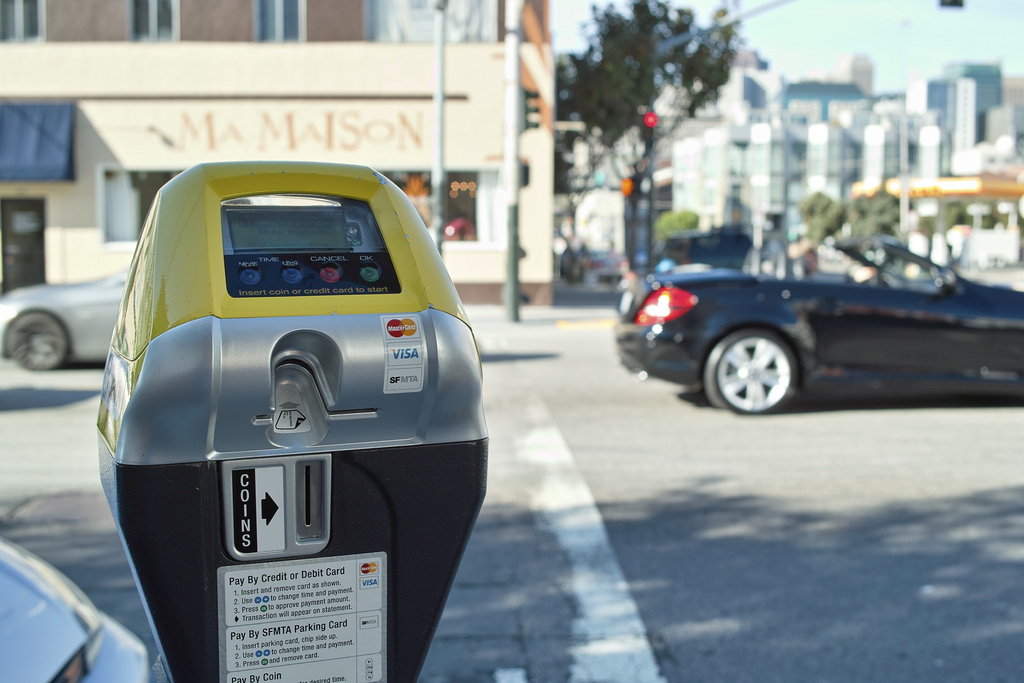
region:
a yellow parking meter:
[91, 149, 490, 678]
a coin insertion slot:
[223, 450, 332, 561]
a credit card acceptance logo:
[382, 313, 428, 396]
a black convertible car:
[607, 234, 1022, 418]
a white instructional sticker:
[218, 551, 392, 679]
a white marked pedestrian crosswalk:
[464, 351, 671, 677]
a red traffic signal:
[641, 109, 660, 148]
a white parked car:
[2, 532, 146, 675]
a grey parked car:
[3, 257, 128, 375]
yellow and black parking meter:
[85, 142, 539, 680]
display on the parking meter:
[223, 196, 360, 255]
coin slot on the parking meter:
[290, 454, 325, 534]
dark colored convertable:
[599, 222, 1023, 435]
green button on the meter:
[357, 259, 390, 291]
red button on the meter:
[313, 250, 346, 288]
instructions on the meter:
[217, 554, 395, 679]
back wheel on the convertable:
[695, 320, 800, 412]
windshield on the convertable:
[855, 225, 970, 289]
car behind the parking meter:
[2, 252, 154, 382]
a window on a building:
[4, 0, 17, 40]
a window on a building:
[136, 1, 150, 37]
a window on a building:
[152, 0, 190, 45]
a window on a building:
[257, 1, 274, 46]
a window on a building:
[289, 0, 306, 42]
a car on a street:
[12, 265, 121, 392]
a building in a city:
[0, 10, 557, 317]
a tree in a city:
[554, 3, 742, 276]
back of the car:
[580, 203, 790, 426]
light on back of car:
[619, 244, 740, 361]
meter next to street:
[28, 136, 548, 674]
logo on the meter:
[353, 287, 459, 418]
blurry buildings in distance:
[632, 98, 947, 261]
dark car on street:
[606, 192, 1022, 499]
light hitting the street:
[730, 395, 959, 551]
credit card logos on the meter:
[380, 309, 431, 401]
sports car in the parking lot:
[604, 220, 1022, 418]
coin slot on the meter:
[294, 455, 321, 539]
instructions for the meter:
[215, 565, 384, 680]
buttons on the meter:
[228, 250, 393, 290]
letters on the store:
[137, 100, 426, 165]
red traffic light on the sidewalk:
[629, 105, 661, 143]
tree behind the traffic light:
[574, 2, 736, 105]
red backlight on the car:
[631, 290, 696, 328]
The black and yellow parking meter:
[51, 146, 557, 674]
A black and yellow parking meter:
[76, 141, 528, 676]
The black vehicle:
[593, 212, 1023, 485]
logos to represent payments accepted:
[379, 307, 428, 402]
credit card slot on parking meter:
[249, 328, 382, 440]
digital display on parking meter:
[230, 190, 380, 293]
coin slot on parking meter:
[220, 453, 326, 570]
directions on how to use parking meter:
[220, 548, 386, 679]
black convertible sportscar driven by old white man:
[637, 232, 1012, 392]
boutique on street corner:
[56, 89, 543, 328]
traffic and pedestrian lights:
[618, 104, 666, 223]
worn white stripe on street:
[509, 386, 639, 680]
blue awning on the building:
[0, 98, 81, 196]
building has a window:
[260, 3, 281, 36]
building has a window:
[159, 2, 176, 37]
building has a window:
[134, 3, 150, 38]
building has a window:
[23, 0, 40, 37]